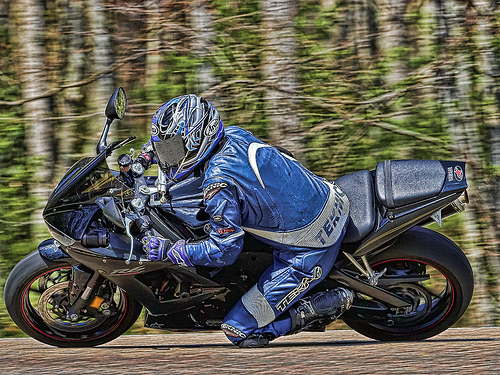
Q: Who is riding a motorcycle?
A: The man.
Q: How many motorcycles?
A: One.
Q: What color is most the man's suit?
A: Blue.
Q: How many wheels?
A: Two.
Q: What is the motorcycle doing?
A: Leaning.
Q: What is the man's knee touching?
A: The road.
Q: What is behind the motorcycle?
A: Trees.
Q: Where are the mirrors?
A: On the motorcycle.